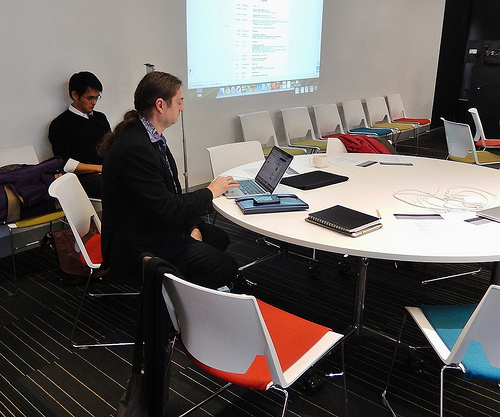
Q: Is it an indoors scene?
A: Yes, it is indoors.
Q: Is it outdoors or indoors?
A: It is indoors.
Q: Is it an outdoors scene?
A: No, it is indoors.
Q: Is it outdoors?
A: No, it is indoors.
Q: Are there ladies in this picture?
A: No, there are no ladies.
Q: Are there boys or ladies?
A: No, there are no ladies or boys.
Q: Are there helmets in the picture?
A: No, there are no helmets.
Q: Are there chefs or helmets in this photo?
A: No, there are no helmets or chefs.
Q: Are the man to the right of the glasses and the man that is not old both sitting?
A: Yes, both the man and the man are sitting.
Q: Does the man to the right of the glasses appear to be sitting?
A: Yes, the man is sitting.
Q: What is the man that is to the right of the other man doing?
A: The man is sitting.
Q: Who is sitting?
A: The man is sitting.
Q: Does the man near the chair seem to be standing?
A: No, the man is sitting.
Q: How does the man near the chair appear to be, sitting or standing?
A: The man is sitting.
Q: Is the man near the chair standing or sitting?
A: The man is sitting.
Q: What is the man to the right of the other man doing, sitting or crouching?
A: The man is sitting.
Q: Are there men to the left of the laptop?
A: Yes, there is a man to the left of the laptop.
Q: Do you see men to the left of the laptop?
A: Yes, there is a man to the left of the laptop.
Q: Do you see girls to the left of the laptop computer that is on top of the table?
A: No, there is a man to the left of the laptop computer.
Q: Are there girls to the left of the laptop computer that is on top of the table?
A: No, there is a man to the left of the laptop computer.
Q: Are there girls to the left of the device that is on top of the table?
A: No, there is a man to the left of the laptop computer.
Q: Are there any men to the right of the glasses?
A: Yes, there is a man to the right of the glasses.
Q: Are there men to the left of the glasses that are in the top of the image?
A: No, the man is to the right of the glasses.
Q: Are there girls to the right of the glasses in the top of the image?
A: No, there is a man to the right of the glasses.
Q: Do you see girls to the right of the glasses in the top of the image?
A: No, there is a man to the right of the glasses.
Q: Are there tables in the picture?
A: Yes, there is a table.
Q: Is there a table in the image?
A: Yes, there is a table.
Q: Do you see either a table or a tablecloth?
A: Yes, there is a table.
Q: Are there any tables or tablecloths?
A: Yes, there is a table.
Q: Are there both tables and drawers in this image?
A: No, there is a table but no drawers.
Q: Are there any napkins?
A: No, there are no napkins.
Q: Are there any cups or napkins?
A: No, there are no napkins or cups.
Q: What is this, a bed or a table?
A: This is a table.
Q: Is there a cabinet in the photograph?
A: No, there are no cabinets.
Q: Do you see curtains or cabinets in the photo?
A: No, there are no cabinets or curtains.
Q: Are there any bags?
A: Yes, there is a bag.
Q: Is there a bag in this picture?
A: Yes, there is a bag.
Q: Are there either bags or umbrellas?
A: Yes, there is a bag.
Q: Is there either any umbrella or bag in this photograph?
A: Yes, there is a bag.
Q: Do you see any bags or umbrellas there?
A: Yes, there is a bag.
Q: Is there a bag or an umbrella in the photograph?
A: Yes, there is a bag.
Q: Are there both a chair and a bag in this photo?
A: Yes, there are both a bag and a chair.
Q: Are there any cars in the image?
A: No, there are no cars.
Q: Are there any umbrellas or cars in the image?
A: No, there are no cars or umbrellas.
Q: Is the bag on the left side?
A: Yes, the bag is on the left of the image.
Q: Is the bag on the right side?
A: No, the bag is on the left of the image.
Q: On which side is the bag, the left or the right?
A: The bag is on the left of the image.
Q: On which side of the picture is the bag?
A: The bag is on the left of the image.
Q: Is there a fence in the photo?
A: No, there are no fences.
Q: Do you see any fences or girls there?
A: No, there are no fences or girls.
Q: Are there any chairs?
A: Yes, there is a chair.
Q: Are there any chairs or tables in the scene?
A: Yes, there is a chair.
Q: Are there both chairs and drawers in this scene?
A: No, there is a chair but no drawers.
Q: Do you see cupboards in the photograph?
A: No, there are no cupboards.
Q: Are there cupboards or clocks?
A: No, there are no cupboards or clocks.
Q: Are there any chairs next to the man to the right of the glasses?
A: Yes, there is a chair next to the man.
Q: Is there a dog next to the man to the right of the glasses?
A: No, there is a chair next to the man.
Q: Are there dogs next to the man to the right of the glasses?
A: No, there is a chair next to the man.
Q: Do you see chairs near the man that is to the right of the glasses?
A: Yes, there is a chair near the man.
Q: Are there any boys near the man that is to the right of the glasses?
A: No, there is a chair near the man.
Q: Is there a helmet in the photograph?
A: No, there are no helmets.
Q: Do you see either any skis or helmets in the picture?
A: No, there are no helmets or skis.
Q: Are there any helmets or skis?
A: No, there are no helmets or skis.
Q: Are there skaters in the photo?
A: No, there are no skaters.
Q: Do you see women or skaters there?
A: No, there are no skaters or women.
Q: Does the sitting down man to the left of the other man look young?
A: Yes, the man is young.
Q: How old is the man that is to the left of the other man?
A: The man is young.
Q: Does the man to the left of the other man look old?
A: No, the man is young.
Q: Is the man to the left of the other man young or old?
A: The man is young.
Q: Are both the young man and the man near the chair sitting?
A: Yes, both the man and the man are sitting.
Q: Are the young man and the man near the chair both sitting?
A: Yes, both the man and the man are sitting.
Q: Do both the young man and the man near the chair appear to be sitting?
A: Yes, both the man and the man are sitting.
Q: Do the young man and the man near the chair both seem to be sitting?
A: Yes, both the man and the man are sitting.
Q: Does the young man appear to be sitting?
A: Yes, the man is sitting.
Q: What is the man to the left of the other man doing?
A: The man is sitting.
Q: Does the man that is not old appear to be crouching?
A: No, the man is sitting.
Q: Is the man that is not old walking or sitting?
A: The man is sitting.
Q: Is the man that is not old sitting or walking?
A: The man is sitting.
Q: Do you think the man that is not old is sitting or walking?
A: The man is sitting.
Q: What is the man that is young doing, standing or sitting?
A: The man is sitting.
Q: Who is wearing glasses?
A: The man is wearing glasses.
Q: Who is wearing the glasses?
A: The man is wearing glasses.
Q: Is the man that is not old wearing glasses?
A: Yes, the man is wearing glasses.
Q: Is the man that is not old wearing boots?
A: No, the man is wearing glasses.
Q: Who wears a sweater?
A: The man wears a sweater.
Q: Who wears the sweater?
A: The man wears a sweater.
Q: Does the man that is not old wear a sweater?
A: Yes, the man wears a sweater.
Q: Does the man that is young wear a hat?
A: No, the man wears a sweater.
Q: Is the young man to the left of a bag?
A: No, the man is to the right of a bag.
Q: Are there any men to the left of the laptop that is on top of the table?
A: Yes, there is a man to the left of the laptop.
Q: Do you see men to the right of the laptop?
A: No, the man is to the left of the laptop.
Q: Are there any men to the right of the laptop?
A: No, the man is to the left of the laptop.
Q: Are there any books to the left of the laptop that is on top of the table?
A: No, there is a man to the left of the laptop.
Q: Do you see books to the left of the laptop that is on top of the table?
A: No, there is a man to the left of the laptop.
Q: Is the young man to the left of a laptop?
A: Yes, the man is to the left of a laptop.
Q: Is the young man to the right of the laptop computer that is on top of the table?
A: No, the man is to the left of the laptop.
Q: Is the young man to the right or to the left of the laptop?
A: The man is to the left of the laptop.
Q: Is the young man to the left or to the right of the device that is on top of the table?
A: The man is to the left of the laptop.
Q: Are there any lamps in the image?
A: No, there are no lamps.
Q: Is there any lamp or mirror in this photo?
A: No, there are no lamps or mirrors.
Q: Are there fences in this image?
A: No, there are no fences.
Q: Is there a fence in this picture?
A: No, there are no fences.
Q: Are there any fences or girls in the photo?
A: No, there are no fences or girls.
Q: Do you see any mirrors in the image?
A: No, there are no mirrors.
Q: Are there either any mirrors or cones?
A: No, there are no mirrors or cones.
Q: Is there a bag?
A: Yes, there is a bag.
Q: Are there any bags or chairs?
A: Yes, there is a bag.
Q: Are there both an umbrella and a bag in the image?
A: No, there is a bag but no umbrellas.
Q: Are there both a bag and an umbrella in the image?
A: No, there is a bag but no umbrellas.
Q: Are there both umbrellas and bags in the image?
A: No, there is a bag but no umbrellas.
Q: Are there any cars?
A: No, there are no cars.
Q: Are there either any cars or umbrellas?
A: No, there are no cars or umbrellas.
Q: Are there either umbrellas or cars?
A: No, there are no cars or umbrellas.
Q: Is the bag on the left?
A: Yes, the bag is on the left of the image.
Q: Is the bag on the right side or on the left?
A: The bag is on the left of the image.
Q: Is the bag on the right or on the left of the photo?
A: The bag is on the left of the image.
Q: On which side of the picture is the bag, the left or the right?
A: The bag is on the left of the image.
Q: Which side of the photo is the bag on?
A: The bag is on the left of the image.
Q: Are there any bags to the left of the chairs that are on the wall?
A: Yes, there is a bag to the left of the chairs.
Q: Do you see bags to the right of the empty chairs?
A: No, the bag is to the left of the chairs.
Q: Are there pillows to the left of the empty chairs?
A: No, there is a bag to the left of the chairs.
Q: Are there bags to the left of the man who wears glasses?
A: Yes, there is a bag to the left of the man.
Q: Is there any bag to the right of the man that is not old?
A: No, the bag is to the left of the man.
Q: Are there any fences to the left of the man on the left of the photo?
A: No, there is a bag to the left of the man.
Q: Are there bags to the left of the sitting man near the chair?
A: Yes, there is a bag to the left of the man.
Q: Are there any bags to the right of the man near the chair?
A: No, the bag is to the left of the man.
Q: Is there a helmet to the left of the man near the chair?
A: No, there is a bag to the left of the man.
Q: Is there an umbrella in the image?
A: No, there are no umbrellas.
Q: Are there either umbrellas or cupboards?
A: No, there are no umbrellas or cupboards.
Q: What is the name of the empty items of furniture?
A: The pieces of furniture are chairs.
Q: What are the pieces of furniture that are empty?
A: The pieces of furniture are chairs.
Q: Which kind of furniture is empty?
A: The furniture is chairs.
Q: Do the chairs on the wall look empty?
A: Yes, the chairs are empty.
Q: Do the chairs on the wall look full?
A: No, the chairs are empty.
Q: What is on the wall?
A: The chairs are on the wall.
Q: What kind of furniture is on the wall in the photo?
A: The pieces of furniture are chairs.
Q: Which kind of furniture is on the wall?
A: The pieces of furniture are chairs.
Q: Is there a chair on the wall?
A: Yes, there are chairs on the wall.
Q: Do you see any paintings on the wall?
A: No, there are chairs on the wall.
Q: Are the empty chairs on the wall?
A: Yes, the chairs are on the wall.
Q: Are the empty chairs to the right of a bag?
A: Yes, the chairs are to the right of a bag.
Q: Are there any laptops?
A: Yes, there is a laptop.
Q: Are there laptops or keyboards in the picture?
A: Yes, there is a laptop.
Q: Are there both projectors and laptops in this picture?
A: No, there is a laptop but no projectors.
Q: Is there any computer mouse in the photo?
A: No, there are no computer mice.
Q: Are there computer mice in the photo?
A: No, there are no computer mice.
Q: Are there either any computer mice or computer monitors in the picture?
A: No, there are no computer mice or computer monitors.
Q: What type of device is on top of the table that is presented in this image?
A: The device is a laptop.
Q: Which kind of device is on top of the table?
A: The device is a laptop.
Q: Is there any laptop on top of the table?
A: Yes, there is a laptop on top of the table.